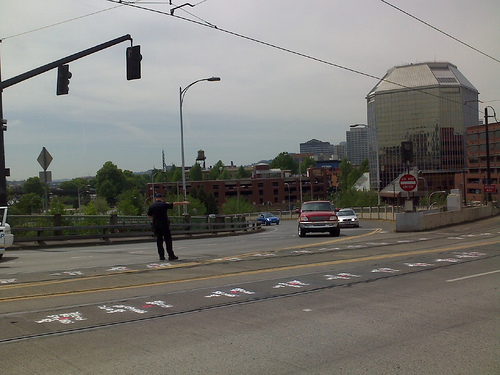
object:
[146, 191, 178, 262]
man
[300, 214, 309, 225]
headlight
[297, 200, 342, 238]
truck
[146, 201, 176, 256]
black outfit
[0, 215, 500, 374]
street